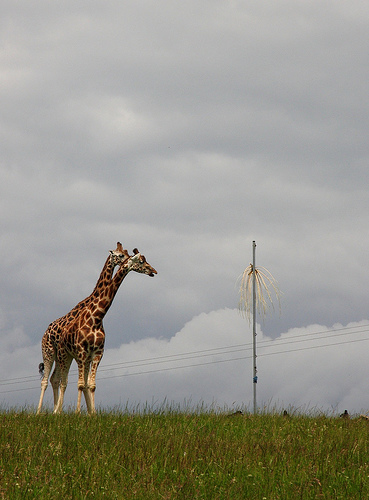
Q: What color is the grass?
A: Green.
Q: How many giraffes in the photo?
A: Two.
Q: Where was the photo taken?
A: In a field.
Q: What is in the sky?
A: Clouds.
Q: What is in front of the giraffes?
A: A pole.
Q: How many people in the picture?
A: None.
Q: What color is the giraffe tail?
A: Black.